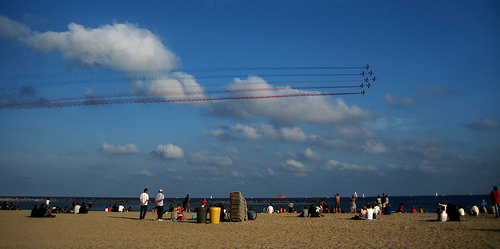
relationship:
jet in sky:
[366, 64, 369, 69] [0, 0, 499, 196]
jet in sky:
[362, 67, 375, 96] [0, 0, 499, 196]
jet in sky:
[369, 70, 373, 75] [0, 0, 499, 196]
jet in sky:
[370, 77, 375, 81] [0, 0, 499, 196]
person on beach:
[139, 188, 150, 219] [0, 206, 499, 249]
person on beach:
[154, 188, 166, 223] [0, 206, 499, 249]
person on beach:
[333, 195, 342, 215] [0, 206, 499, 249]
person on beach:
[349, 193, 357, 214] [0, 206, 499, 249]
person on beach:
[490, 186, 500, 220] [0, 206, 499, 249]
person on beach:
[266, 203, 273, 215] [0, 206, 499, 249]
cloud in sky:
[29, 19, 204, 112] [0, 0, 499, 196]